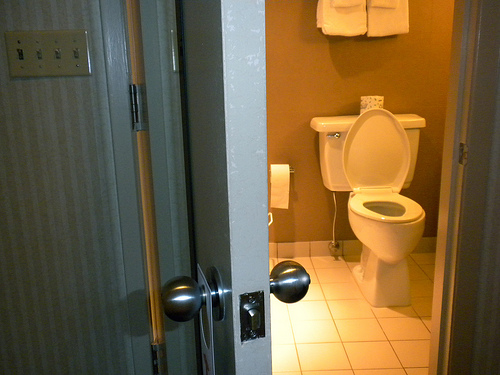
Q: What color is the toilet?
A: White.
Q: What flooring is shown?
A: Tile.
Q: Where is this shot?
A: Bathroom.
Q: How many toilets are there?
A: 1.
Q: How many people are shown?
A: 0.